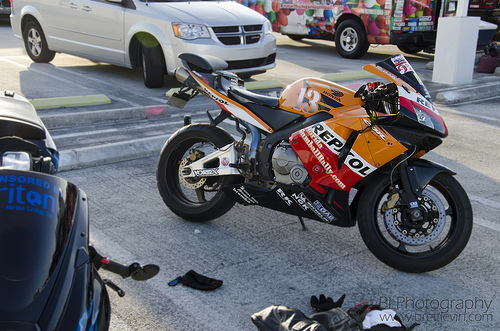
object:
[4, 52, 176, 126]
line